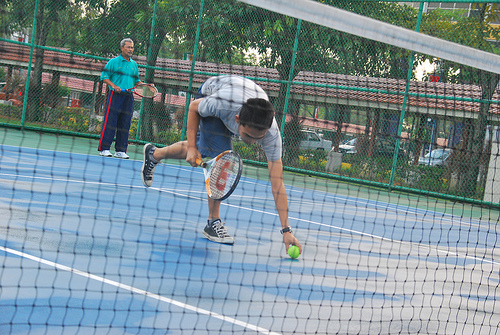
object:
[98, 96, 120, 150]
leg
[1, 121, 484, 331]
ground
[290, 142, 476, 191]
street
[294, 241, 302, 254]
fingers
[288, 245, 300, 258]
ball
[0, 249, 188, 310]
line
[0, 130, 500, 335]
court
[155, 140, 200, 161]
leg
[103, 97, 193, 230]
air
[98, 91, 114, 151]
stripe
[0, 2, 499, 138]
fence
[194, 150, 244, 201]
racket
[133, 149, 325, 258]
front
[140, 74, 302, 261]
man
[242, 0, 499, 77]
stripe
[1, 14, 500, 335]
net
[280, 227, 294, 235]
watch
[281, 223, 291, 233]
wrist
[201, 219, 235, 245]
shoe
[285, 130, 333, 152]
car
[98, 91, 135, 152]
pants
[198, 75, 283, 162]
shirt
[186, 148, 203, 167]
hand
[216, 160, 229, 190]
w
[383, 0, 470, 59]
leaves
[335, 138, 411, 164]
cars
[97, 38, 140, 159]
man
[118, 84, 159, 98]
racket